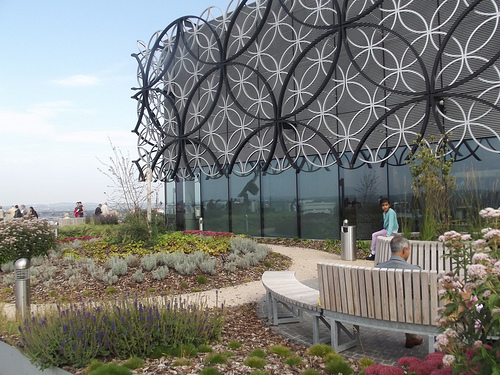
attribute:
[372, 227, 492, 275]
bench — for seating, backless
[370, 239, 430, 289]
man — old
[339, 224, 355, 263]
trash can — silver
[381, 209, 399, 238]
shirt — blue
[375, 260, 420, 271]
shirt — gray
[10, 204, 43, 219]
people — walking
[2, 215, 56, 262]
flowers — light pink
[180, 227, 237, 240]
flowers — purple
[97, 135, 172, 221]
trees — small, bare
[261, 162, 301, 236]
window — large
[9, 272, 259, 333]
space — green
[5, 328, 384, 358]
space — green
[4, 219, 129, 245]
space — green